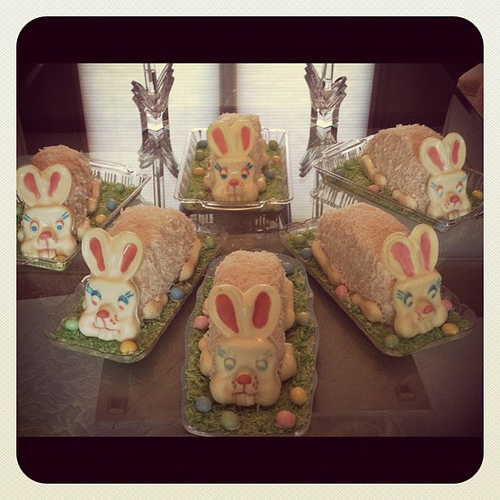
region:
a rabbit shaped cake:
[183, 238, 328, 439]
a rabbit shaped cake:
[307, 196, 471, 367]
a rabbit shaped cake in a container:
[170, 118, 295, 215]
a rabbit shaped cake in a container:
[310, 125, 481, 221]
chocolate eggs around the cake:
[184, 248, 321, 443]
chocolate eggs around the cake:
[60, 205, 194, 367]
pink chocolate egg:
[276, 400, 298, 431]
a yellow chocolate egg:
[114, 333, 141, 356]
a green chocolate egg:
[61, 313, 84, 336]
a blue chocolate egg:
[165, 280, 187, 301]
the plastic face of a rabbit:
[15, 166, 79, 261]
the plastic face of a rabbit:
[76, 224, 147, 343]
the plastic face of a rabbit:
[202, 280, 292, 407]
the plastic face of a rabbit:
[380, 219, 453, 336]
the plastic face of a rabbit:
[418, 133, 473, 224]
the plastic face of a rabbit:
[201, 101, 272, 198]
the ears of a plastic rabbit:
[202, 278, 288, 336]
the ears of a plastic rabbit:
[366, 224, 446, 274]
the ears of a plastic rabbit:
[75, 226, 151, 282]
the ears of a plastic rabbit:
[16, 159, 78, 208]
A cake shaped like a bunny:
[181, 242, 330, 435]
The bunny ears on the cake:
[207, 270, 287, 340]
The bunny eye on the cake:
[216, 349, 272, 376]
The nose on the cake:
[228, 369, 259, 389]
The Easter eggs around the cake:
[190, 385, 312, 431]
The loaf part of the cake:
[325, 202, 401, 320]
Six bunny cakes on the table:
[19, 108, 479, 442]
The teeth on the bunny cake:
[36, 245, 62, 266]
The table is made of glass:
[32, 58, 454, 158]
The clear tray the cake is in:
[93, 152, 170, 222]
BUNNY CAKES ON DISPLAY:
[30, 119, 460, 427]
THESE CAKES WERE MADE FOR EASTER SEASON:
[21, 104, 488, 386]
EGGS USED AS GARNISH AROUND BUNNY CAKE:
[195, 373, 310, 429]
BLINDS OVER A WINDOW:
[59, 57, 377, 235]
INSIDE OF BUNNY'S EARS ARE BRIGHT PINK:
[192, 283, 298, 344]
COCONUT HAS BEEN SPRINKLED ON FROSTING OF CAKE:
[84, 202, 209, 299]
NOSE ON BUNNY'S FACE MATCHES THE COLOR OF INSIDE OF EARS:
[232, 365, 270, 388]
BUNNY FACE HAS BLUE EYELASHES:
[75, 277, 145, 300]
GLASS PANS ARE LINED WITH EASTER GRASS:
[193, 229, 304, 427]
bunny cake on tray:
[192, 113, 277, 208]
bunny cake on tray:
[204, 235, 308, 445]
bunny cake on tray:
[313, 203, 439, 315]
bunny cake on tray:
[103, 206, 173, 348]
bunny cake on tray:
[23, 150, 90, 259]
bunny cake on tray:
[366, 122, 470, 213]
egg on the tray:
[270, 410, 298, 430]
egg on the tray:
[192, 398, 213, 414]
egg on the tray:
[118, 342, 137, 355]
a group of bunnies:
[13, 91, 498, 450]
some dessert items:
[12, 80, 498, 455]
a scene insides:
[33, 80, 487, 420]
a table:
[36, 138, 474, 498]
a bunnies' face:
[189, 269, 299, 425]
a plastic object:
[128, 75, 188, 119]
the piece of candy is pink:
[335, 283, 348, 301]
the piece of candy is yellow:
[290, 386, 308, 406]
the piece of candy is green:
[221, 409, 238, 429]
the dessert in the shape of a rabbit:
[199, 250, 295, 403]